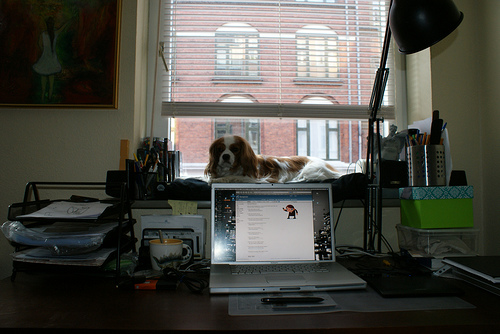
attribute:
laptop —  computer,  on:
[194, 157, 374, 309]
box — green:
[397, 183, 476, 226]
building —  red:
[160, 7, 442, 209]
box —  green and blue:
[397, 183, 474, 230]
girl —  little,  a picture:
[22, 6, 71, 88]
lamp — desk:
[331, 12, 477, 293]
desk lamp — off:
[359, 0, 465, 265]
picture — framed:
[2, 1, 120, 112]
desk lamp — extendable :
[359, 43, 397, 245]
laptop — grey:
[209, 188, 369, 297]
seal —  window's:
[174, 172, 363, 182]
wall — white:
[3, 1, 151, 208]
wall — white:
[394, 0, 497, 256]